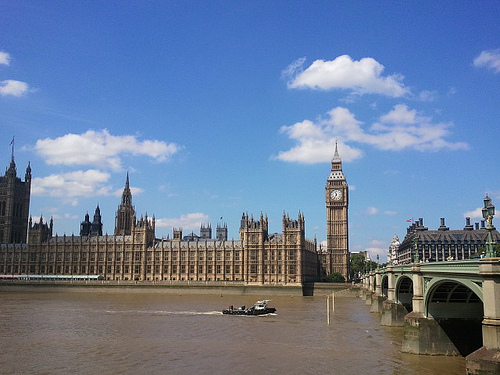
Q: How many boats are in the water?
A: One.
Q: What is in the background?
A: Buildings.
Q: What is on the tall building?
A: Clock.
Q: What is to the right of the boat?
A: Bridge.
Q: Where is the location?
A: London.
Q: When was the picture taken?
A: Daytime.